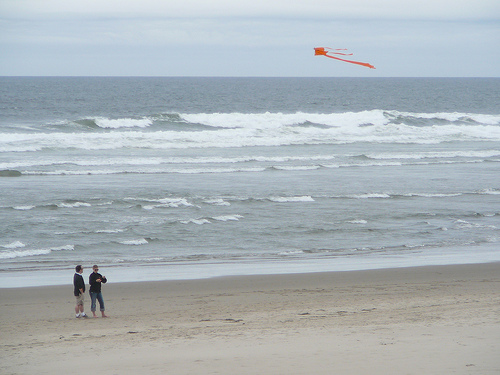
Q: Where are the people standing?
A: On the sand.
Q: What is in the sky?
A: An orange kite.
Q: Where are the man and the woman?
A: At the beach.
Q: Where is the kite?
A: In the air.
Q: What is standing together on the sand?
A: Two people.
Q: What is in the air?
A: The kite.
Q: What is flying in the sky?
A: The kite.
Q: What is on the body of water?
A: The waves.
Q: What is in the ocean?
A: The waves.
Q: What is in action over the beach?
A: The orange kite.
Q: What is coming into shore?
A: The wave.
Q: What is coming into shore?
A: The crest of the wave.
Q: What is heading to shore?
A: Choppy water and waves.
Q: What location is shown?
A: Beach.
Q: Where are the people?
A: On the sand.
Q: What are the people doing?
A: Flying kite.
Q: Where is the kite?
A: IN the sky.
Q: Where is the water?
A: Behind the beach.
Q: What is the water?
A: Ocean.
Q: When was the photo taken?
A: Daytime.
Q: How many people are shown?
A: Two.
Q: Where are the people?
A: Beach.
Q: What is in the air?
A: Kite.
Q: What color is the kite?
A: Red.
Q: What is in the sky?
A: Clouds.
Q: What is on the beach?
A: Sand.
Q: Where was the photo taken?
A: At the beach.